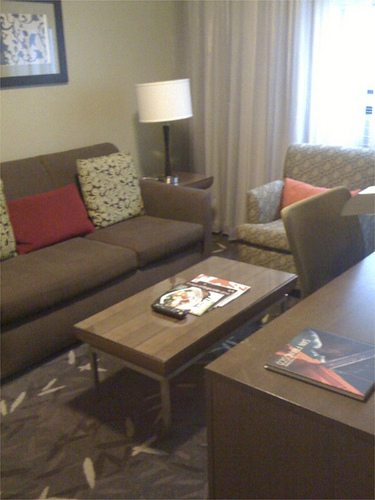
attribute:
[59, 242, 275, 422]
table — wooden, metal, brown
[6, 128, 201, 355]
couch — brown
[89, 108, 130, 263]
cushion — flowered, floral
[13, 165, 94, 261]
cushion — red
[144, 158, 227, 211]
end table — brown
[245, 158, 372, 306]
chair — stuffed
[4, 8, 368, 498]
living room — small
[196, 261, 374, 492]
desk — office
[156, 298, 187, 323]
remote — for tv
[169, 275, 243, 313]
magazines — for leisure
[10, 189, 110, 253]
pillow — red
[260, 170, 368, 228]
pillow — orange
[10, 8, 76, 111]
picture — decorative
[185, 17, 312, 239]
curtains — beige, white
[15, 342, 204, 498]
carpet — abstract, patterned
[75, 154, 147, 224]
pillow — tan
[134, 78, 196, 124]
shade — white